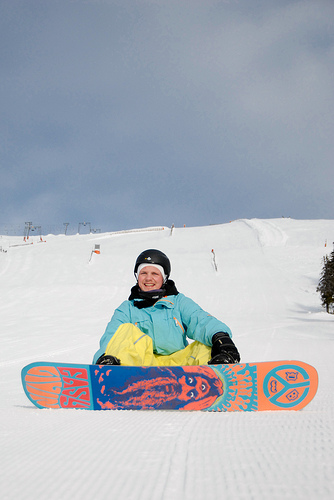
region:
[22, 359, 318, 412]
a 60's style snow board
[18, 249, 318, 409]
a man laying in snow with snowboard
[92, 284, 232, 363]
a light blue winter coat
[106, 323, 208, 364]
a pair of yellow snow pants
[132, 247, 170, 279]
a black safety helmet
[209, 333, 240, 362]
a black snow glove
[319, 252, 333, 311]
large green tree in distance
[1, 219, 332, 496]
a large snowy hillside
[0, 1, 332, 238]
a hazy blue sky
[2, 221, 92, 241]
a ski lift system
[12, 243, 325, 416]
a snowboarded posing with his board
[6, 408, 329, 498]
the snow looks carefully manicured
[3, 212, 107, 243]
ski lift in the background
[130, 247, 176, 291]
snowboard dude is wearing a helmet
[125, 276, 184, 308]
snowboard dude is wearing a muffler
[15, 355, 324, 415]
snowboard is custom painted with a scary face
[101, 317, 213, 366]
snowboard dude is wearing yellow baggy pants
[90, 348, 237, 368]
snowboard dude's boots are basic black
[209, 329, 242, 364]
snowboard dude is wearing black gloves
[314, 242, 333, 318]
a tree growing in the background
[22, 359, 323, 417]
snowboard in the snow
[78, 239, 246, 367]
person sitting in the snow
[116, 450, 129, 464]
patch of white snow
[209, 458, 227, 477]
patch of white snow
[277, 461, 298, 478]
patch of white snow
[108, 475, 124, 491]
patch of white snow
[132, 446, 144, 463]
patch of white snow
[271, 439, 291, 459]
patch of white snow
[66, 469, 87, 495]
patch of white snow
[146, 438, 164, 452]
patch of white snow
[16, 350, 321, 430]
snow board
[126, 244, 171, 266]
black helmet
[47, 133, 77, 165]
white clouds in blue sky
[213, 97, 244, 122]
white clouds in blue sky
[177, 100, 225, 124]
white clouds in blue sky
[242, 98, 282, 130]
white clouds in blue sky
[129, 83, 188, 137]
white clouds in blue sky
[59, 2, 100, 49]
white clouds in blue sky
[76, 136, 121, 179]
white clouds in blue sky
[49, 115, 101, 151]
white clouds in blue sky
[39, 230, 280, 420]
person on snow board with yellow pants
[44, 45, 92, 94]
white clouds in blue sky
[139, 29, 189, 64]
white clouds in blue sky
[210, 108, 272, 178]
white clouds in blue sky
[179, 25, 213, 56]
white clouds in blue sky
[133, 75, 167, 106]
white clouds in blue sky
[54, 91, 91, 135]
white clouds in blue sky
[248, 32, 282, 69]
white clouds in blue sky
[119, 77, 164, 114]
white clouds in blue sky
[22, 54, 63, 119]
white clouds in blue sky